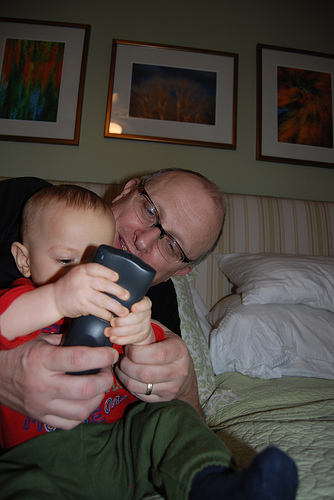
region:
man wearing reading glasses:
[127, 179, 201, 269]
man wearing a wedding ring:
[142, 382, 156, 397]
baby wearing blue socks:
[196, 454, 293, 497]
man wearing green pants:
[5, 431, 218, 494]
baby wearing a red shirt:
[11, 280, 167, 420]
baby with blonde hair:
[29, 180, 110, 250]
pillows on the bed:
[230, 248, 327, 370]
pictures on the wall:
[105, 27, 244, 162]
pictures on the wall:
[255, 30, 333, 217]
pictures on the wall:
[2, 13, 91, 149]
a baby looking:
[1, 183, 298, 497]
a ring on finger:
[145, 380, 154, 397]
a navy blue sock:
[189, 441, 302, 497]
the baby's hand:
[52, 260, 157, 345]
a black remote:
[59, 243, 156, 379]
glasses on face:
[130, 174, 196, 267]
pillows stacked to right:
[204, 249, 332, 380]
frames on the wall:
[0, 13, 333, 169]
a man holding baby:
[0, 165, 228, 497]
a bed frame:
[0, 174, 331, 330]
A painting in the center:
[116, 58, 228, 131]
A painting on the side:
[1, 30, 71, 133]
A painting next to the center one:
[265, 60, 333, 153]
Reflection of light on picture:
[110, 125, 118, 131]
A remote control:
[112, 257, 135, 268]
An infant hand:
[93, 266, 105, 313]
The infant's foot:
[263, 455, 285, 497]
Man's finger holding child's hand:
[133, 347, 170, 360]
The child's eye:
[59, 259, 71, 262]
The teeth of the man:
[122, 243, 123, 247]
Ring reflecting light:
[149, 383, 150, 391]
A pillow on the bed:
[250, 315, 276, 376]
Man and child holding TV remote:
[0, 166, 300, 498]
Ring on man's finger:
[144, 383, 153, 397]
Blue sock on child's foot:
[185, 443, 300, 498]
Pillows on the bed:
[208, 250, 330, 378]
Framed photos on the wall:
[0, 16, 333, 164]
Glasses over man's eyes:
[135, 176, 194, 266]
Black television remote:
[59, 244, 154, 353]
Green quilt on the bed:
[204, 388, 331, 497]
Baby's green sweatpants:
[0, 393, 235, 496]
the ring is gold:
[145, 382, 151, 393]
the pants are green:
[0, 397, 235, 499]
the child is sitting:
[0, 181, 299, 496]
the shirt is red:
[1, 277, 164, 450]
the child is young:
[0, 184, 298, 497]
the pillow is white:
[215, 249, 332, 311]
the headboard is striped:
[0, 176, 333, 311]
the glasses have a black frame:
[132, 177, 197, 264]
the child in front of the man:
[1, 167, 297, 498]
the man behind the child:
[0, 167, 296, 499]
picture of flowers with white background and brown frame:
[254, 40, 332, 172]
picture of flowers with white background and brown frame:
[101, 38, 241, 151]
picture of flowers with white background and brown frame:
[0, 14, 92, 146]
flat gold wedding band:
[145, 381, 154, 395]